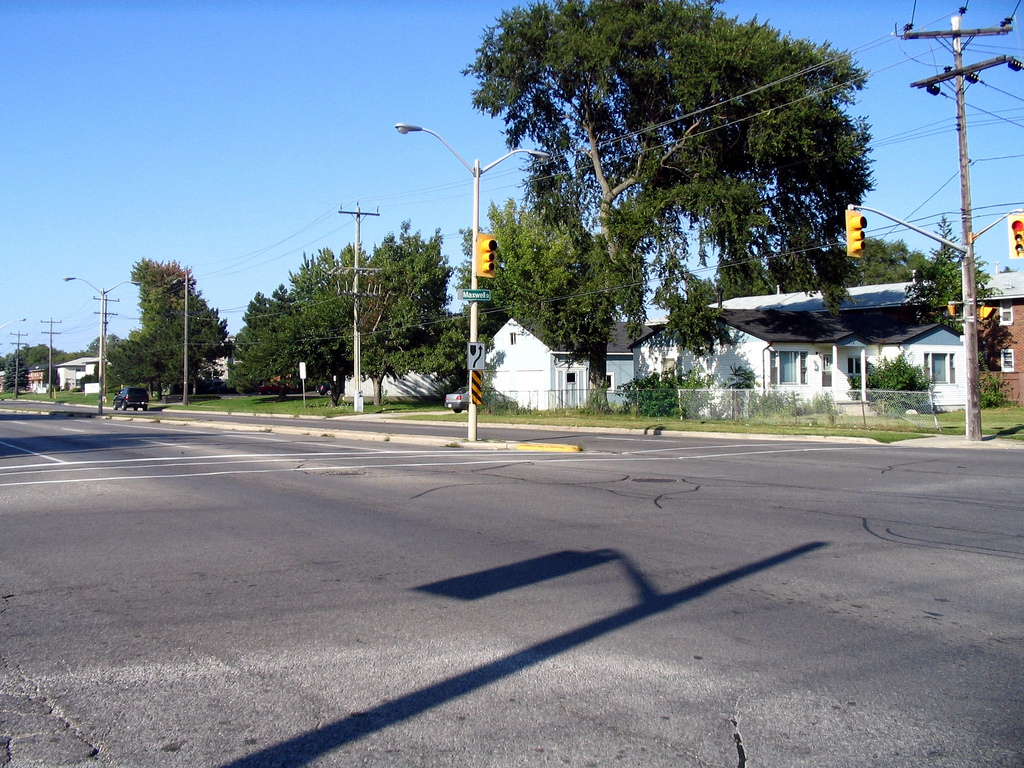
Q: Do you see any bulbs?
A: No, there are no bulbs.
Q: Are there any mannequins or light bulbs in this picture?
A: No, there are no light bulbs or mannequins.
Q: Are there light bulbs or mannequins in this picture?
A: No, there are no light bulbs or mannequins.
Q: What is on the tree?
A: The leaves are on the tree.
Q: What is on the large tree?
A: The leaves are on the tree.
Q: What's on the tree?
A: The leaves are on the tree.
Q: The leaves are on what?
A: The leaves are on the tree.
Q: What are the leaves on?
A: The leaves are on the tree.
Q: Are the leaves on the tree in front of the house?
A: Yes, the leaves are on the tree.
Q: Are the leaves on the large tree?
A: Yes, the leaves are on the tree.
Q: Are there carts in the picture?
A: No, there are no carts.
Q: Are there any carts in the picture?
A: No, there are no carts.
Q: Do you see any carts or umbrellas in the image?
A: No, there are no carts or umbrellas.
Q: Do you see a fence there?
A: Yes, there is a fence.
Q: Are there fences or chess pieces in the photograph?
A: Yes, there is a fence.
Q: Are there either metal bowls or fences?
A: Yes, there is a metal fence.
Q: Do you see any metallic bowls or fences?
A: Yes, there is a metal fence.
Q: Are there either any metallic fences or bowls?
A: Yes, there is a metal fence.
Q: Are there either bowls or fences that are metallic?
A: Yes, the fence is metallic.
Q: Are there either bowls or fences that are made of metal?
A: Yes, the fence is made of metal.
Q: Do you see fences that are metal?
A: Yes, there is a metal fence.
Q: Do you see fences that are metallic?
A: Yes, there is a fence that is metallic.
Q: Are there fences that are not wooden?
A: Yes, there is a metallic fence.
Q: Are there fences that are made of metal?
A: Yes, there is a fence that is made of metal.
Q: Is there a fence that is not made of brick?
A: Yes, there is a fence that is made of metal.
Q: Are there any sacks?
A: No, there are no sacks.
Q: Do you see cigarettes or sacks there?
A: No, there are no sacks or cigarettes.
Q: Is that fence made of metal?
A: Yes, the fence is made of metal.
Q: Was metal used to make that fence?
A: Yes, the fence is made of metal.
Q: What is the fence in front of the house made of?
A: The fence is made of metal.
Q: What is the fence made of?
A: The fence is made of metal.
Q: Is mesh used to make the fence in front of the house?
A: No, the fence is made of metal.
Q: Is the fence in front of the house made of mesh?
A: No, the fence is made of metal.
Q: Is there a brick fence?
A: No, there is a fence but it is made of metal.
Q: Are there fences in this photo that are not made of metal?
A: No, there is a fence but it is made of metal.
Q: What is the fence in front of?
A: The fence is in front of the house.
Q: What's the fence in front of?
A: The fence is in front of the house.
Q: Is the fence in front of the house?
A: Yes, the fence is in front of the house.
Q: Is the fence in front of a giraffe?
A: No, the fence is in front of the house.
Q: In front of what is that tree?
A: The tree is in front of the house.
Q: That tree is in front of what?
A: The tree is in front of the house.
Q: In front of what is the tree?
A: The tree is in front of the house.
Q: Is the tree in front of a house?
A: Yes, the tree is in front of a house.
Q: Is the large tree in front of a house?
A: Yes, the tree is in front of a house.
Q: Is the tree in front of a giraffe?
A: No, the tree is in front of a house.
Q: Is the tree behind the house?
A: No, the tree is in front of the house.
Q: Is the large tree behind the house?
A: No, the tree is in front of the house.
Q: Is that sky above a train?
A: No, the sky is above the house.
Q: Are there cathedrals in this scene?
A: No, there are no cathedrals.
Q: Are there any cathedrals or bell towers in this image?
A: No, there are no cathedrals or bell towers.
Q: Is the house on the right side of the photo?
A: Yes, the house is on the right of the image.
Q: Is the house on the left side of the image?
A: No, the house is on the right of the image.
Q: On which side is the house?
A: The house is on the right of the image.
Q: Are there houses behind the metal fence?
A: Yes, there is a house behind the fence.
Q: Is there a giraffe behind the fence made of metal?
A: No, there is a house behind the fence.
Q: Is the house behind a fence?
A: Yes, the house is behind a fence.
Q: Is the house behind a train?
A: No, the house is behind a fence.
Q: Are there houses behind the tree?
A: Yes, there is a house behind the tree.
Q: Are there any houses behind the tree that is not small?
A: Yes, there is a house behind the tree.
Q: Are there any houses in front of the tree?
A: No, the house is behind the tree.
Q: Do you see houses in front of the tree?
A: No, the house is behind the tree.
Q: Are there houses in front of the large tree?
A: No, the house is behind the tree.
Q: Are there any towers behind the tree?
A: No, there is a house behind the tree.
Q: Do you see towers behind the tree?
A: No, there is a house behind the tree.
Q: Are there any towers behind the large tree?
A: No, there is a house behind the tree.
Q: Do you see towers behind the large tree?
A: No, there is a house behind the tree.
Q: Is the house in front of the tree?
A: No, the house is behind the tree.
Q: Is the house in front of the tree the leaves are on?
A: No, the house is behind the tree.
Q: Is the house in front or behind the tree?
A: The house is behind the tree.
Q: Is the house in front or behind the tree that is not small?
A: The house is behind the tree.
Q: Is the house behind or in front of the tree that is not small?
A: The house is behind the tree.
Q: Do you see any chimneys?
A: No, there are no chimneys.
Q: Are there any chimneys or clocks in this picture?
A: No, there are no chimneys or clocks.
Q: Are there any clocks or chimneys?
A: No, there are no chimneys or clocks.